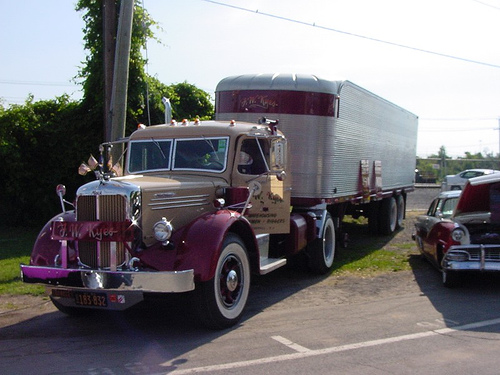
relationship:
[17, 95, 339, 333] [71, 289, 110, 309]
tractor has plates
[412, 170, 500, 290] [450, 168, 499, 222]
classic car has a hood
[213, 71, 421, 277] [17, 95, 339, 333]
trailer hooked to tractor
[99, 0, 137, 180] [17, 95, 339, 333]
poles behind tractor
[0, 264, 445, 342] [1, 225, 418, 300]
dirt patch near edge of grass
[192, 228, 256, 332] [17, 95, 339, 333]
driver's steer tire on tractor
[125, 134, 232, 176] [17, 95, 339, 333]
split windshield on tractor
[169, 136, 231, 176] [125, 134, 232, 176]
left pane of split windshield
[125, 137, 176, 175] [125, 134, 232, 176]
right pane of split windshield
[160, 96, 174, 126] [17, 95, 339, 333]
exhaust pipe on tractor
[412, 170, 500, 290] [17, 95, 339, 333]
classic car parked near tractor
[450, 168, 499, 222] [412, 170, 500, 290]
hood opened on classic car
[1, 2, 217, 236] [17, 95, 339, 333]
vines behind tractor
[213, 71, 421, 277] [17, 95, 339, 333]
trailer attached to tractor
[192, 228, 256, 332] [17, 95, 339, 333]
driver's steer tire of tractor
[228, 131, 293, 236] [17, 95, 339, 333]
open door on tractor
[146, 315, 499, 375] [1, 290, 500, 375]
parking lines one tarmac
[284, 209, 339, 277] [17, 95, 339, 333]
drive tire on tractor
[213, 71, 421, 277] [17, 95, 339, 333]
trailer behind tractor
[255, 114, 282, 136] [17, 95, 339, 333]
air horn on tractor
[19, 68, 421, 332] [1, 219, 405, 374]
tractor-trailer has a shadow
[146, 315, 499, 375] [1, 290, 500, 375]
parking lines on tarmac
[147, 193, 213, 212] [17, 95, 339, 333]
chrome trim on tractor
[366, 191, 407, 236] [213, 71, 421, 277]
trailer tires on trailer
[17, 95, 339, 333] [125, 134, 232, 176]
tractor has split windshield